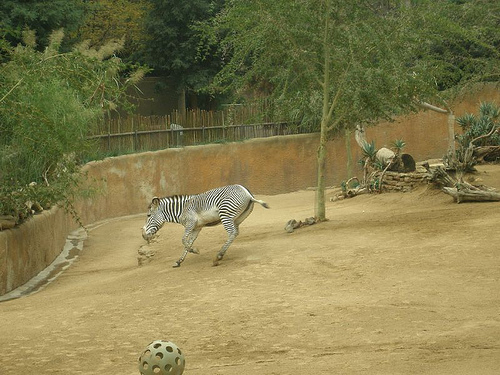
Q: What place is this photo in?
A: It is at the pen.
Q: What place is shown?
A: It is a pen.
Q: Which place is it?
A: It is a pen.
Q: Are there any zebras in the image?
A: Yes, there is a zebra.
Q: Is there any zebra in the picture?
A: Yes, there is a zebra.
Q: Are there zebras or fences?
A: Yes, there is a zebra.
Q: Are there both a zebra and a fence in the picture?
A: Yes, there are both a zebra and a fence.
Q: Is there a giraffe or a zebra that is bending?
A: Yes, the zebra is bending.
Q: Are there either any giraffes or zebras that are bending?
A: Yes, the zebra is bending.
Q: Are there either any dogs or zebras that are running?
A: Yes, the zebra is running.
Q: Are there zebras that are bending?
A: Yes, there is a zebra that is bending.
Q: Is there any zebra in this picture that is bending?
A: Yes, there is a zebra that is bending.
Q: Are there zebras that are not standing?
A: Yes, there is a zebra that is bending.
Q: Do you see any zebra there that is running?
A: Yes, there is a zebra that is running.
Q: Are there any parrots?
A: No, there are no parrots.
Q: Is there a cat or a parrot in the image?
A: No, there are no parrots or cats.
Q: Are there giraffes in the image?
A: No, there are no giraffes.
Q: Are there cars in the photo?
A: No, there are no cars.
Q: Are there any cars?
A: No, there are no cars.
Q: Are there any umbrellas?
A: No, there are no umbrellas.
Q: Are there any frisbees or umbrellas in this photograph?
A: No, there are no umbrellas or frisbees.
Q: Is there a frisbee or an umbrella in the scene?
A: No, there are no umbrellas or frisbees.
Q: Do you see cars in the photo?
A: No, there are no cars.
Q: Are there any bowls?
A: No, there are no bowls.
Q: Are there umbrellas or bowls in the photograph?
A: No, there are no bowls or umbrellas.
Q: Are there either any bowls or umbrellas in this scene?
A: No, there are no bowls or umbrellas.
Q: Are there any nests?
A: No, there are no nests.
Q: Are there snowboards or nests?
A: No, there are no nests or snowboards.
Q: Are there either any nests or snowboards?
A: No, there are no nests or snowboards.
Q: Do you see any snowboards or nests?
A: No, there are no nests or snowboards.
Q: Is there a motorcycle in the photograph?
A: No, there are no motorcycles.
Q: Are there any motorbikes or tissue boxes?
A: No, there are no motorbikes or tissue boxes.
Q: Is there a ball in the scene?
A: Yes, there is a ball.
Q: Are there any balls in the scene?
A: Yes, there is a ball.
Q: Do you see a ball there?
A: Yes, there is a ball.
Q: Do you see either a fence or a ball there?
A: Yes, there is a ball.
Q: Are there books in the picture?
A: No, there are no books.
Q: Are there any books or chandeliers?
A: No, there are no books or chandeliers.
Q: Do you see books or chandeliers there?
A: No, there are no books or chandeliers.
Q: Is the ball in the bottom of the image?
A: Yes, the ball is in the bottom of the image.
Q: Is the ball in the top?
A: No, the ball is in the bottom of the image.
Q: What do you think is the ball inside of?
A: The ball is inside the pen.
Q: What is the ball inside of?
A: The ball is inside the pen.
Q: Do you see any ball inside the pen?
A: Yes, there is a ball inside the pen.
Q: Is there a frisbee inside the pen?
A: No, there is a ball inside the pen.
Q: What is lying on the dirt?
A: The ball is lying on the dirt.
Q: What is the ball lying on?
A: The ball is lying on the dirt.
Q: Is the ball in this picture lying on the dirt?
A: Yes, the ball is lying on the dirt.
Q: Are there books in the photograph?
A: No, there are no books.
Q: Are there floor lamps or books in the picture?
A: No, there are no books or floor lamps.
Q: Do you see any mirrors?
A: No, there are no mirrors.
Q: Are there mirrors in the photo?
A: No, there are no mirrors.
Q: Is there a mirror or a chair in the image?
A: No, there are no mirrors or chairs.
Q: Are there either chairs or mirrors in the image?
A: No, there are no mirrors or chairs.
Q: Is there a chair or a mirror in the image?
A: No, there are no mirrors or chairs.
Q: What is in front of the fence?
A: The wall is in front of the fence.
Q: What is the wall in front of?
A: The wall is in front of the fence.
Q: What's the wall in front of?
A: The wall is in front of the fence.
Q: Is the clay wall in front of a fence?
A: Yes, the wall is in front of a fence.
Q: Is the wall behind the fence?
A: No, the wall is in front of the fence.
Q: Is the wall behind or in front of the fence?
A: The wall is in front of the fence.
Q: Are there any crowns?
A: No, there are no crowns.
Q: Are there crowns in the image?
A: No, there are no crowns.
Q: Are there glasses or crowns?
A: No, there are no crowns or glasses.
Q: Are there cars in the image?
A: No, there are no cars.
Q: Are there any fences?
A: Yes, there is a fence.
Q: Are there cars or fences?
A: Yes, there is a fence.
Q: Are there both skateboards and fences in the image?
A: No, there is a fence but no skateboards.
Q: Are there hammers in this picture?
A: No, there are no hammers.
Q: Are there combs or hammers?
A: No, there are no hammers or combs.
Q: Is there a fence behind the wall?
A: Yes, there is a fence behind the wall.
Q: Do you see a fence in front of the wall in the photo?
A: No, the fence is behind the wall.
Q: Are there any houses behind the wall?
A: No, there is a fence behind the wall.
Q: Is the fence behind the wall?
A: Yes, the fence is behind the wall.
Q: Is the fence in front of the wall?
A: No, the fence is behind the wall.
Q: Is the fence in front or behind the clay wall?
A: The fence is behind the wall.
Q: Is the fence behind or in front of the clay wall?
A: The fence is behind the wall.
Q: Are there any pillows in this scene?
A: No, there are no pillows.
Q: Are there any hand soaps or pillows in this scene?
A: No, there are no pillows or hand soaps.